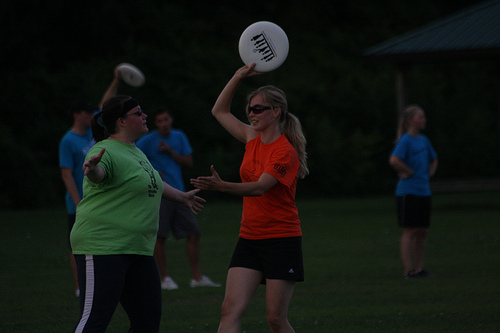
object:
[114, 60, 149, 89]
frisbee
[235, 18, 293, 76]
frisbee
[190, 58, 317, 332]
woman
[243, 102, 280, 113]
sunglasses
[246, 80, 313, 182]
hair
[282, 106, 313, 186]
ponytail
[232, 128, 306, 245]
shirt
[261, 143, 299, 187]
sleeve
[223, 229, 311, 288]
shorts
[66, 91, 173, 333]
woman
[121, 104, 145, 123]
sunglasses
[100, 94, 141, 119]
headband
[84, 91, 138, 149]
hair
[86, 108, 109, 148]
ponytail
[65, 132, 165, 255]
shirt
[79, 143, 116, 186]
sleeve